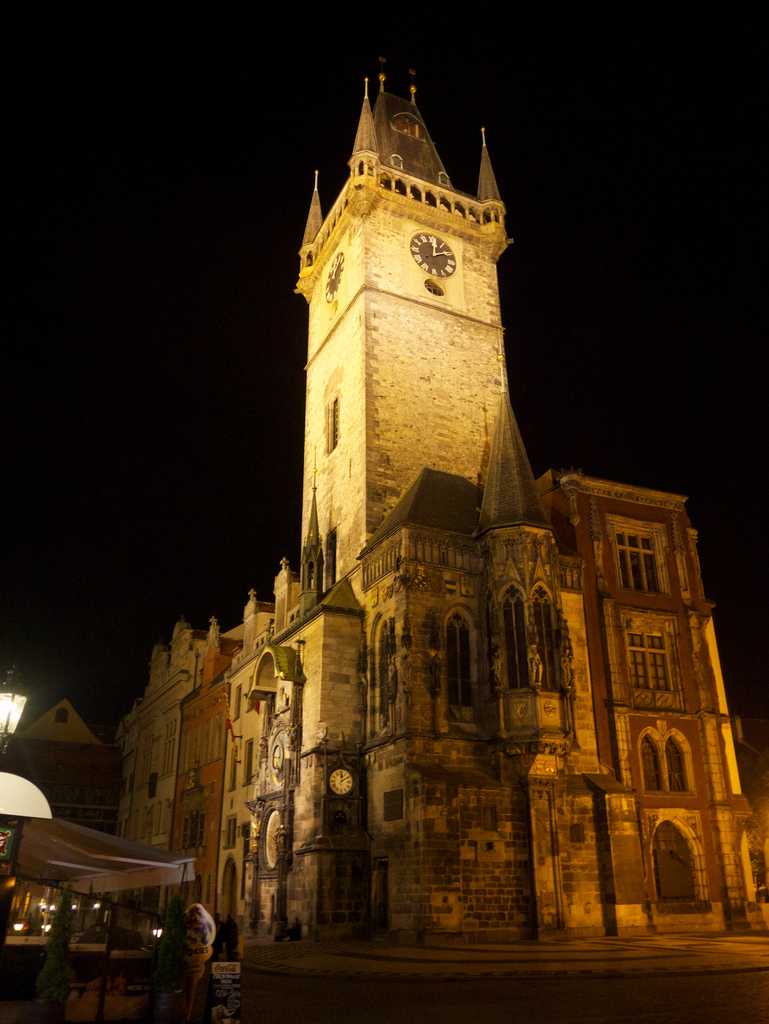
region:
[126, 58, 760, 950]
large tan building at night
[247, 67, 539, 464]
tall tan clock tower at night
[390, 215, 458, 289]
clock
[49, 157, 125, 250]
black colored sky at night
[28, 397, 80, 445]
black colored sky at night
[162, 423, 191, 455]
black colored sky at night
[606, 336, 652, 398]
black colored sky at night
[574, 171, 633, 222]
black colored sky at night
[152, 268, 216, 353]
black colored sky at night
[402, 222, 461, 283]
large clock at top of tower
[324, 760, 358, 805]
clock on lower stone pillar on building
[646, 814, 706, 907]
brown door on side of building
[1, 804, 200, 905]
white tent covering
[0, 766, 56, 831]
white arched dome light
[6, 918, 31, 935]
small yellow light on street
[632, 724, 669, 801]
arched window on front of building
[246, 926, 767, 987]
paved sidewalk in front of building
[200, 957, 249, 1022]
upright sign on sidewalk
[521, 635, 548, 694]
small statue of person on front of building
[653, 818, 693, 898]
arched entrance to the structure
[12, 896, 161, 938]
cluster of lights on the side of the structure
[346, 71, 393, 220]
one of three turrets at the top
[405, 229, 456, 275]
face of the clock on the front top of the structure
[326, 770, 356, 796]
face of the lowest clock on the structure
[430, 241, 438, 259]
white hand of the clock pointing straight upward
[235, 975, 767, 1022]
pavement in front of the structure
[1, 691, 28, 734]
two rectangular light bars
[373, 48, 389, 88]
one of the two uppermost projections at the top of the structure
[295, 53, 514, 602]
A tall clock tower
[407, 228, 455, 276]
face of a clock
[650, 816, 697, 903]
an arch-shaped door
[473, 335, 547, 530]
an ornate spire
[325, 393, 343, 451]
a window on a clock tower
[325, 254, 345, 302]
another clock face on a clock tower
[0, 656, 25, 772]
A brightly glowing streetlight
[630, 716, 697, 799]
a pair of arched windows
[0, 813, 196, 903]
a canvas awning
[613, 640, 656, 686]
a window on the building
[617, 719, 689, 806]
a window on the building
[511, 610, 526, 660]
a window on the building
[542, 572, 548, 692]
a window on the building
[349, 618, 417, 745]
a window on the building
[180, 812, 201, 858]
a window on the building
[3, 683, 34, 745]
The black street light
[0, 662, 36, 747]
A black street light